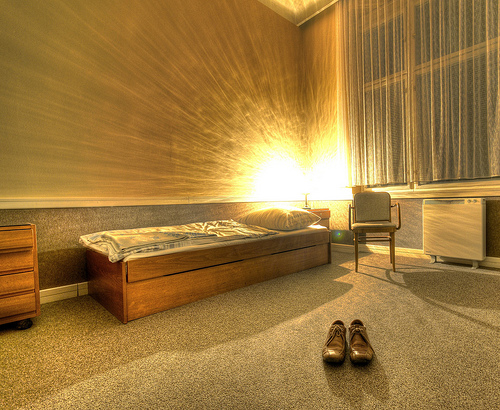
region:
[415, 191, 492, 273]
A radiator.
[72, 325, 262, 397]
Carpet.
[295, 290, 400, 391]
A pair of brown shoes.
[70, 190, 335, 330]
A bed for a single person.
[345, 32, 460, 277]
A chair is near the window.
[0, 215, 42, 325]
A dresser.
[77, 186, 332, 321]
The bed frame is made from wood.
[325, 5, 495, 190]
A large window.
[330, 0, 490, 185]
Drapes are in front of the window.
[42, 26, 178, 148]
The walls are cream colored.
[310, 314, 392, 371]
pair of tan loafers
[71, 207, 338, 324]
small bed with wooden base and white and blue covers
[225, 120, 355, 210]
bright yellow and orange light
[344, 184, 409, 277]
wooden upholstered chair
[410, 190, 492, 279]
small white air conditioning unit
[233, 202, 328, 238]
white and blue pillow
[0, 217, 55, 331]
small wooden dresser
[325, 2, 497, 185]
pair of windows with a closed lace curtain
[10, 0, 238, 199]
rays of yellow light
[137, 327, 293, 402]
mottled gray carpet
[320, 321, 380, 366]
a pair of brown shoes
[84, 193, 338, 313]
a bed with a wooden bed frame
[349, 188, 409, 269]
a simple upholstered chair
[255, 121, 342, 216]
a bright light shining in the corner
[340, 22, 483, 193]
sheer curtains covering a large windown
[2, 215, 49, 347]
a brown chest of drawers.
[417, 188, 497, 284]
an air conditioning unit on the wall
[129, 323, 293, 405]
a grey drab carpet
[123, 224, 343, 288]
a bed frame with a built in drawer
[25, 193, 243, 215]
a white chair rail on the wall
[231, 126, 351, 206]
Light in corner of room is very bright.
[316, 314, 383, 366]
Shoes sitting in middle of floor.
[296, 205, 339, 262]
Light is sitting on nightstand.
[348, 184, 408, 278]
Chair near corner of room.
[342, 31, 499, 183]
Windows have curtains on them.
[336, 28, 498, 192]
The curtains are pulled shut.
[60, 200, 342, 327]
Captains bed pushed against wall.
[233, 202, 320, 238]
There's a pillow on the bed.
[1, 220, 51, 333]
There's a small stand at end of bed.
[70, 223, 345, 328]
The bed is all wood.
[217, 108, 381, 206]
bright light coming into room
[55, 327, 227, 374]
large shadow on the carpet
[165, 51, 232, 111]
reflections on the wall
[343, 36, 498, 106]
edge of window panes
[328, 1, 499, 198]
sheer curtains in the window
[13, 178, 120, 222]
edge of the wall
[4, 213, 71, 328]
brown small dresser cabinet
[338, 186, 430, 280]
brown chair with tan seat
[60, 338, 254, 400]
light brown carpet on the floor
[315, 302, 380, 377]
pair of brown shoes